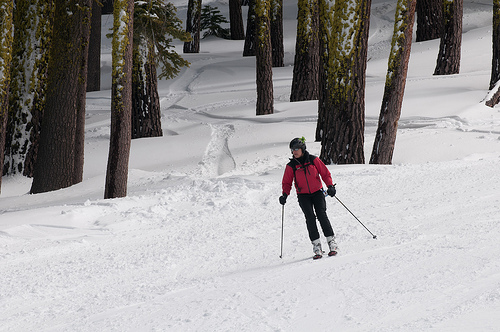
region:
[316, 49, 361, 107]
mould is on the tree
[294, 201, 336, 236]
the pants are black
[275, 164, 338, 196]
the jacket is pink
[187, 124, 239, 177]
snow trails are on the ground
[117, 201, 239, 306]
the snow is whte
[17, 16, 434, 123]
trees are close together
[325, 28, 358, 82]
the mould is green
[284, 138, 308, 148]
the helmet is black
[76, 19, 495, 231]
the ground is sloppy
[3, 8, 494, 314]
it is daylight in the photo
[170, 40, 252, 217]
A kiers trail through vthe trees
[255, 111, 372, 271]
A kier on the main trail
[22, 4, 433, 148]
Trees on the ski trail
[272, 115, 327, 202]
A red winter coat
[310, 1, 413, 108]
Moss growing on the trees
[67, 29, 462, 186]
The trail goes in many ways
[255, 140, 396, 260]
Ready to head down hill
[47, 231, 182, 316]
Snow on the main trail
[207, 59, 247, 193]
Some un bothered snow on the trail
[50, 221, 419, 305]
Lots of white snow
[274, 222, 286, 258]
ski pole in skier's right hand.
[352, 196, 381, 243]
ski pole in skier's left hand.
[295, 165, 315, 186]
red coat on skier.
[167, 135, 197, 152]
snow on the ground.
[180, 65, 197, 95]
path through the snow.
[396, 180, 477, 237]
ski tracks in the snow.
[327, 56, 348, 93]
moss on the tree.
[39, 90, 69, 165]
trunk of the tree.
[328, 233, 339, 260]
boot on skier's foot.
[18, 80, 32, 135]
snow on the tree.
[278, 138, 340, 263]
a woman skiing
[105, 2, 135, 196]
a brown tree trunk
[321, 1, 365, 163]
a brown tree trunk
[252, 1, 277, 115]
a brown tree trunk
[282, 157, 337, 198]
the bright pink jacket of the woman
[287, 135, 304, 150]
a black helmet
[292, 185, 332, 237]
a black pair of ski pants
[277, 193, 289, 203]
a black ski glove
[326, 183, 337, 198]
a black ski glove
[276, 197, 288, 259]
a black ski pole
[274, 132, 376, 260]
a skier going downhill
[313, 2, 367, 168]
a large snowy tree trunk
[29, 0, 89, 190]
a large snowy tree trunk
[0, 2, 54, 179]
a large snowy tree trunk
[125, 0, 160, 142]
a large snowy tree trunk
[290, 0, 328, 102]
a large snowy tree trunk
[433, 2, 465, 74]
a large snowy tree trunk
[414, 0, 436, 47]
a large snowy tree trunk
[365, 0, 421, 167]
a small snowy tree trunk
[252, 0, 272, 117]
a small snowy tree trunk